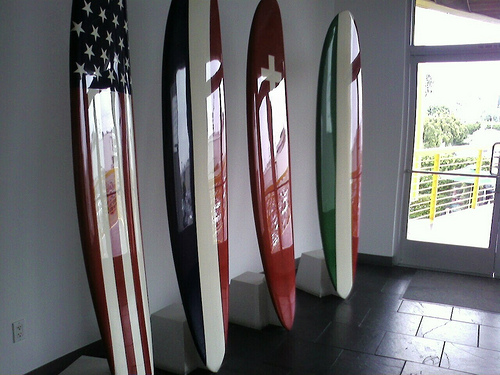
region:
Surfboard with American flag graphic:
[67, 3, 161, 374]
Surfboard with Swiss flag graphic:
[240, 1, 303, 333]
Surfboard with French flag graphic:
[159, 1, 237, 373]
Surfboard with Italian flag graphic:
[312, 10, 365, 304]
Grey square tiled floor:
[32, 249, 498, 371]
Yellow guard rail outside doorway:
[406, 148, 497, 226]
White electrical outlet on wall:
[8, 314, 28, 346]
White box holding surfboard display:
[228, 267, 290, 338]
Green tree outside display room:
[408, 102, 466, 221]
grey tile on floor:
[382, 277, 407, 296]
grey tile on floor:
[356, 289, 401, 312]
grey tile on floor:
[398, 295, 452, 317]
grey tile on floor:
[451, 305, 497, 324]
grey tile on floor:
[479, 323, 499, 351]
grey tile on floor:
[415, 313, 479, 348]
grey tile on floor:
[361, 306, 420, 332]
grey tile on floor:
[438, 339, 496, 371]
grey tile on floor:
[376, 330, 443, 367]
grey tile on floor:
[324, 319, 381, 355]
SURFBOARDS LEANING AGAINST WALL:
[67, 106, 379, 371]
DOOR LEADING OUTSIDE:
[385, 34, 496, 259]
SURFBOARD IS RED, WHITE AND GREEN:
[317, 7, 379, 302]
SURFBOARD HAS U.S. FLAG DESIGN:
[69, 19, 132, 293]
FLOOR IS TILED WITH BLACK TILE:
[243, 256, 484, 370]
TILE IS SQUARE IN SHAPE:
[415, 306, 483, 351]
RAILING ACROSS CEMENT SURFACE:
[401, 139, 495, 221]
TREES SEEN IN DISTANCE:
[417, 99, 496, 155]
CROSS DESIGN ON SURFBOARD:
[239, 36, 304, 130]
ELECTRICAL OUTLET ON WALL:
[7, 312, 39, 352]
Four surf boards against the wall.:
[59, 50, 371, 373]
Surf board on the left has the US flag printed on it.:
[77, 5, 149, 370]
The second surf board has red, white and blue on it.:
[161, 3, 233, 366]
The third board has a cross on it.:
[255, 11, 295, 324]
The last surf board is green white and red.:
[315, 15, 360, 297]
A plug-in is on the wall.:
[10, 316, 23, 341]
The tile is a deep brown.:
[295, 302, 496, 365]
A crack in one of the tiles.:
[420, 315, 477, 345]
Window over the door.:
[406, 5, 496, 46]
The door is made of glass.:
[408, 60, 498, 249]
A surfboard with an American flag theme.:
[64, 0, 160, 374]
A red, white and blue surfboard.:
[155, 0, 245, 370]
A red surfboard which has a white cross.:
[243, 0, 303, 336]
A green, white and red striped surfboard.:
[312, 3, 372, 308]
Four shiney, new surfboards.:
[62, 2, 382, 372]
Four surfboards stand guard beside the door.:
[64, 0, 497, 360]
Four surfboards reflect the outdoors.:
[64, 2, 374, 372]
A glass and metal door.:
[389, 2, 498, 298]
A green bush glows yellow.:
[422, 102, 483, 155]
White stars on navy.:
[79, 12, 123, 56]